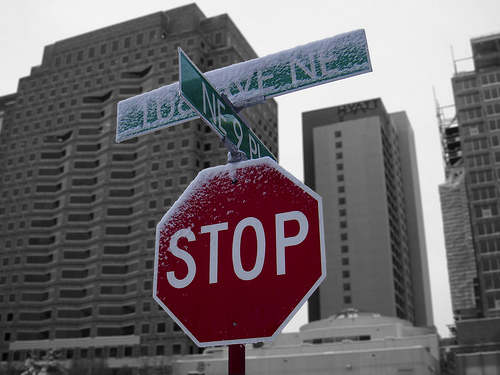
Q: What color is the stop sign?
A: Red and white.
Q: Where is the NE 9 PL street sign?
A: Above the stop sign.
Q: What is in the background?
A: The tall Hyatt building.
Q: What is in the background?
A: A tall gray building.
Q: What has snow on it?
A: A stop sign.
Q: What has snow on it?
A: A street sign.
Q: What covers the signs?
A: Snow.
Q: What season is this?
A: Winter.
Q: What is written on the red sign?
A: Stop.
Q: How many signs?
A: Three.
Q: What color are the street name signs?
A: Green.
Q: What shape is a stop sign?
A: Octagon.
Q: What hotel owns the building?
A: Hyatt.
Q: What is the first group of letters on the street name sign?
A: NE.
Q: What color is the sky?
A: Grey.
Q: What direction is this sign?
A: Northeast.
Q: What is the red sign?
A: A stop sign.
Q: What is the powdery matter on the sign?
A: Snow.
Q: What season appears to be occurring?
A: Winter.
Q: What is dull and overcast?
A: The sky.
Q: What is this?
A: A city scene.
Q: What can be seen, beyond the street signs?
A: Several grey highrise buildings.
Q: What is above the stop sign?
A: Two, green street signs.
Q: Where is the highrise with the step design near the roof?
A: To the far left of the highrise buildings.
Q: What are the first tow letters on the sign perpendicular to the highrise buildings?
A: NE.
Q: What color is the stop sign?
A: Red.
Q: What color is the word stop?
A: White.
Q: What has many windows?
A: Buildings.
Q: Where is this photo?
A: City.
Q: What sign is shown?
A: Stop.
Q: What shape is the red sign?
A: Hexagon.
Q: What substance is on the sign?
A: Snow.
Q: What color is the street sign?
A: Green.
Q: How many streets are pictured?
A: Two.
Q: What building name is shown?
A: Hyatt.